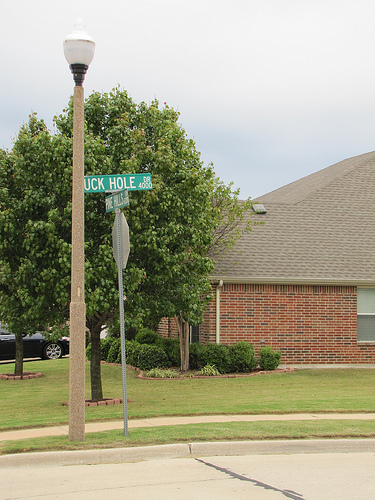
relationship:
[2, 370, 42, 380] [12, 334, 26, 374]
bricks around bottom of tree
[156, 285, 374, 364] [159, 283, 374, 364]
wall made of bricks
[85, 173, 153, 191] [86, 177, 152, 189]
sign has white writing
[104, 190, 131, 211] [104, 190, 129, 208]
sign has white writing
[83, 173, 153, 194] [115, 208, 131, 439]
sign on a sign post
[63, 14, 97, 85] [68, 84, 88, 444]
street light on post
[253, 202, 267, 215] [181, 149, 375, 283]
skylight on roof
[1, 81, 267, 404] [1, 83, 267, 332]
tree has foliage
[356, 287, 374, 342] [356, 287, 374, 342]
trim has trim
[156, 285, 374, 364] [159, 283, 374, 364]
walls are made of bricks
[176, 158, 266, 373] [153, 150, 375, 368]
tree beside house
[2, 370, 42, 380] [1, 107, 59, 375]
landscaping around tree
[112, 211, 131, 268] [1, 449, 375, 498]
stop sign next to street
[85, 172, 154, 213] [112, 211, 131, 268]
street names above stop sign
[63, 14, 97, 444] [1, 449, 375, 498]
lamp post on side of road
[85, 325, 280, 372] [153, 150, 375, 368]
bushes around house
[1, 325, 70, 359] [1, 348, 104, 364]
car in driveway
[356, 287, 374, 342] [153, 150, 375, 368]
trim on side of house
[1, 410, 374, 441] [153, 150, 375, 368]
sidewalk next to house